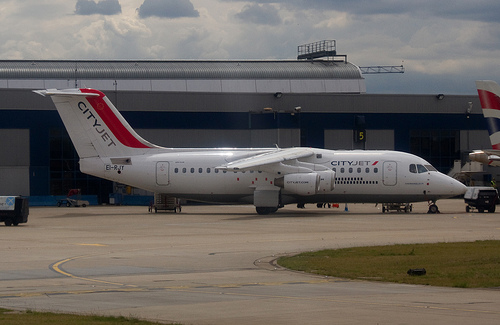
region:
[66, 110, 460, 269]
plane at the airport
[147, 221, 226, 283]
cement below the plane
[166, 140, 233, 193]
windows on the plane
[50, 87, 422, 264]
red and white plane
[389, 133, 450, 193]
front of the plane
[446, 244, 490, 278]
green grass next to plane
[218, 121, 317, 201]
wing of the plane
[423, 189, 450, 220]
wheel of the plane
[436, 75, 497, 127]
tail of the plane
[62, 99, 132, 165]
words on the plane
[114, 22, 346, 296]
the plane is white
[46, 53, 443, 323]
the plane is white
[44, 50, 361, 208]
the plane is white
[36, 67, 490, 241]
A City Jet passenger plane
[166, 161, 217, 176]
windows of an airplane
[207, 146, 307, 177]
a right wing of an airplane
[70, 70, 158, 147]
a vertical stabilizer of an airplane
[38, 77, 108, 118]
a horizontal stabilizer of an airplane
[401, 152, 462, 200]
cockpit of an airplane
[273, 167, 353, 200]
right side turbine engine of an airplane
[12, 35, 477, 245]
a white and red passenger plane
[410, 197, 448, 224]
landing gear of an airplane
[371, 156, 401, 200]
door of an airplane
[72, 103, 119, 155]
CityJet is written on the tail of the plane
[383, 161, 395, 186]
the door behind the pilots cockpit is white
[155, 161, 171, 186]
white door at the back of the plane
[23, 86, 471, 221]
plane sitting on the tarmac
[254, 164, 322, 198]
one of 2 engines visable under the wing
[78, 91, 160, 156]
a red stripe on the tail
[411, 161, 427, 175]
side windows in the cockpit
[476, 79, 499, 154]
partial tail of red, white and blue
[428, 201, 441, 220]
landing gear on the plane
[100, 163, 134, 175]
call numbers on the side of the plane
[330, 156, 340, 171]
the black letter C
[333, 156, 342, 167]
the black letter I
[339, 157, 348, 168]
the black letter T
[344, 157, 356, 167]
the black letter Y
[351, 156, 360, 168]
the gray letter J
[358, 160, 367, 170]
the gray letter E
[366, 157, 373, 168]
the gray letter T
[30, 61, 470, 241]
this is a plane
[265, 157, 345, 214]
these are the engines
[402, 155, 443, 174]
this is the windshield